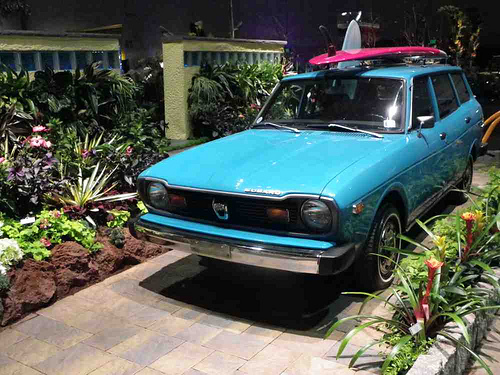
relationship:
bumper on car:
[132, 213, 327, 280] [123, 44, 484, 259]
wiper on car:
[326, 122, 381, 139] [125, 61, 491, 292]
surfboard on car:
[306, 45, 451, 68] [125, 61, 491, 292]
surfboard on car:
[331, 20, 363, 100] [125, 61, 491, 292]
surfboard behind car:
[306, 45, 451, 68] [125, 61, 491, 292]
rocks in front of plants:
[1, 217, 110, 296] [0, 159, 148, 290]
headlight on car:
[298, 197, 333, 235] [125, 61, 491, 292]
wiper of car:
[330, 122, 382, 139] [125, 61, 491, 292]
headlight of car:
[301, 204, 333, 238] [125, 61, 491, 292]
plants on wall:
[192, 65, 258, 125] [155, 42, 290, 110]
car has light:
[125, 61, 491, 292] [294, 193, 335, 233]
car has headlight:
[125, 61, 491, 292] [146, 180, 171, 210]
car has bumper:
[125, 61, 491, 292] [126, 209, 357, 278]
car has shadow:
[125, 61, 491, 292] [144, 245, 334, 336]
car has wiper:
[125, 61, 491, 292] [325, 120, 385, 138]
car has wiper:
[125, 61, 491, 292] [253, 122, 299, 132]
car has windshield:
[125, 61, 491, 292] [260, 75, 408, 136]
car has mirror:
[184, 64, 499, 278] [401, 114, 453, 148]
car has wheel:
[125, 61, 491, 292] [363, 205, 411, 291]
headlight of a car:
[146, 180, 175, 214] [125, 61, 491, 292]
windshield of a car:
[252, 72, 408, 135] [125, 61, 491, 292]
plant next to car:
[47, 154, 136, 214] [125, 61, 491, 292]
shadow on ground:
[137, 250, 366, 341] [1, 252, 331, 374]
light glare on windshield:
[380, 82, 407, 128] [257, 78, 408, 132]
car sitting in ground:
[125, 61, 491, 292] [0, 152, 499, 374]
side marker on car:
[349, 197, 369, 214] [125, 61, 491, 292]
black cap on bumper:
[323, 239, 355, 279] [128, 215, 360, 276]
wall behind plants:
[161, 42, 192, 142] [0, 50, 283, 280]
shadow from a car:
[138, 239, 360, 334] [125, 61, 491, 292]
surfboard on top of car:
[286, 31, 474, 90] [125, 61, 491, 292]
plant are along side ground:
[39, 158, 141, 214] [0, 152, 499, 374]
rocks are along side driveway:
[0, 256, 59, 328] [4, 255, 331, 373]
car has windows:
[125, 61, 491, 292] [432, 75, 462, 122]